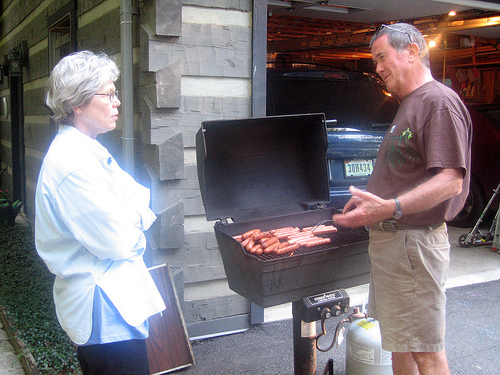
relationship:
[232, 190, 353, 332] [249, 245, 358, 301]
hotdogs on barbecue grill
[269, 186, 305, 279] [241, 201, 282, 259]
row of uncooked hotdogs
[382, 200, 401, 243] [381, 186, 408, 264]
watch on wrist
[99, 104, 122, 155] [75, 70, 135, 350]
eyes glasses on woman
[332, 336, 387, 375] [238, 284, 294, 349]
propane tank next to grill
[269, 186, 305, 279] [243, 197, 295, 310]
row of cooked hot dogs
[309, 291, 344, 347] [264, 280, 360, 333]
knobs on front of grill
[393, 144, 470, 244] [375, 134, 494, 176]
dark lavender short sleeve t-shirt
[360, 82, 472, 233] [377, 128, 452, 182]
t shirt man wearing a t shirt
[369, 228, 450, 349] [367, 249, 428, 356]
shorts man wearing shorts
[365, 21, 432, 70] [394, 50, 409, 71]
hair man has grey hair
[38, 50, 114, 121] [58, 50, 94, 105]
hair woman has grey hair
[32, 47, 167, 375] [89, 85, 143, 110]
lady wearing glasses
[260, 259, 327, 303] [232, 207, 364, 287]
these are hotdogs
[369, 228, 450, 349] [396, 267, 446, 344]
shorts are khaki shorts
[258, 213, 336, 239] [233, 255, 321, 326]
meat cooking on a bbq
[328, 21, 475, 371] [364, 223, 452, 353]
man wearing shorts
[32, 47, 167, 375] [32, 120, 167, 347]
lady wearing shirt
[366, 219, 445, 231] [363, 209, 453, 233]
belt worn around waist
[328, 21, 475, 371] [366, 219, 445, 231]
man wearing belt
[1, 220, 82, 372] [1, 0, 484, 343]
area planted next to building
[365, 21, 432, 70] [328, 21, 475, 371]
hair belonging to man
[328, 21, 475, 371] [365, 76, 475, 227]
man wearing shirt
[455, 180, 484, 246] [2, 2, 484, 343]
scooter standing in garage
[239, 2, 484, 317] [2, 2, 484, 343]
garage parked in garage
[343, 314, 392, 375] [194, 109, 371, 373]
propane attached to grill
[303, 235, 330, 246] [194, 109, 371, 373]
hot dog cooking on grill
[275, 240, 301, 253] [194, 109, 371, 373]
hot dog cooking on grill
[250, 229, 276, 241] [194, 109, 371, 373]
hot dog cooking on grill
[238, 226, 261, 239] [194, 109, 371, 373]
hot dog cooking on grill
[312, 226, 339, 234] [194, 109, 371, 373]
hot dog cooking on grill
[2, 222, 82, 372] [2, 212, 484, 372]
plant growing in ground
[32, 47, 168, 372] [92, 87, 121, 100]
lady wearing glasses